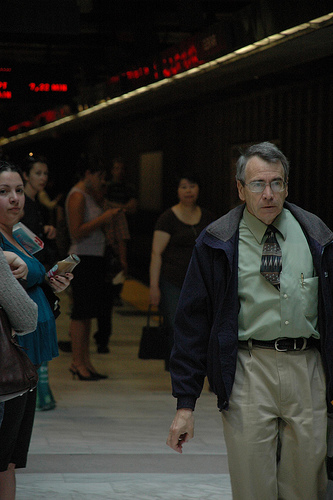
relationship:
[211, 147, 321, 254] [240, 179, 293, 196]
man with eyeglasses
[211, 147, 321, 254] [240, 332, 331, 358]
man wearing belt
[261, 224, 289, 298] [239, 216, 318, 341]
necktie on shirt